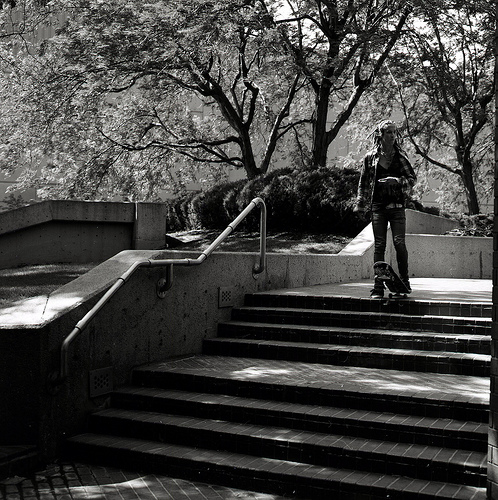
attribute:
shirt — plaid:
[353, 149, 418, 213]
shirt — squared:
[356, 150, 417, 207]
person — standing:
[350, 104, 421, 307]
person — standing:
[351, 111, 428, 300]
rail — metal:
[57, 195, 266, 399]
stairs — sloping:
[64, 290, 496, 497]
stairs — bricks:
[239, 296, 467, 378]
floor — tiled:
[198, 385, 328, 485]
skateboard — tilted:
[371, 259, 410, 299]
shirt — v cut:
[374, 155, 404, 176]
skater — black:
[372, 253, 405, 296]